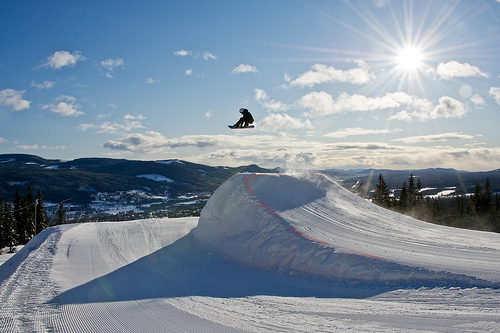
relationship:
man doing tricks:
[235, 106, 255, 122] [208, 104, 259, 137]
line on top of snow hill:
[237, 167, 308, 237] [212, 168, 427, 279]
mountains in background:
[75, 156, 173, 183] [26, 146, 220, 176]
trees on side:
[0, 209, 41, 246] [3, 245, 30, 274]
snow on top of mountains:
[96, 308, 269, 323] [75, 156, 173, 183]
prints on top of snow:
[246, 306, 308, 319] [96, 308, 269, 323]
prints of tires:
[246, 306, 308, 319] [236, 307, 313, 318]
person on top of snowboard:
[235, 106, 255, 122] [219, 123, 259, 135]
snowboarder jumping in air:
[197, 93, 263, 135] [203, 48, 296, 74]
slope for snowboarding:
[285, 172, 396, 243] [219, 123, 259, 135]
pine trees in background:
[373, 180, 438, 215] [26, 146, 220, 176]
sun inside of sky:
[399, 52, 430, 85] [254, 8, 452, 124]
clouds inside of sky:
[299, 63, 390, 114] [254, 8, 452, 124]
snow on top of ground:
[96, 308, 269, 323] [124, 282, 218, 322]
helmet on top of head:
[240, 108, 243, 113] [238, 108, 248, 112]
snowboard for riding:
[219, 123, 259, 135] [229, 109, 256, 132]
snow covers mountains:
[96, 308, 269, 323] [75, 156, 173, 183]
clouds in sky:
[299, 63, 390, 114] [254, 8, 452, 124]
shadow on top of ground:
[85, 254, 294, 306] [124, 282, 218, 322]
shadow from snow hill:
[85, 254, 294, 306] [212, 168, 427, 279]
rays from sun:
[325, 48, 376, 74] [399, 52, 430, 85]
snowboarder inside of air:
[197, 93, 263, 135] [203, 48, 296, 74]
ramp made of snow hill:
[237, 170, 331, 191] [212, 168, 427, 279]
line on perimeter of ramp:
[237, 167, 308, 237] [237, 170, 331, 191]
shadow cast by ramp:
[85, 254, 294, 306] [237, 170, 331, 191]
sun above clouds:
[399, 52, 430, 85] [299, 63, 390, 114]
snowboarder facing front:
[197, 93, 263, 135] [227, 109, 240, 126]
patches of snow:
[175, 301, 209, 321] [96, 308, 269, 323]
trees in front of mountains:
[0, 209, 41, 246] [75, 156, 173, 183]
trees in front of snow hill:
[0, 209, 41, 246] [212, 168, 427, 279]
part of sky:
[67, 1, 128, 13] [254, 8, 452, 124]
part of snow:
[60, 226, 118, 246] [96, 308, 269, 323]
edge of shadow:
[21, 238, 47, 250] [85, 254, 294, 306]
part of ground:
[129, 314, 186, 323] [124, 282, 218, 322]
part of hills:
[73, 170, 92, 180] [12, 150, 179, 208]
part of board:
[247, 125, 255, 130] [224, 122, 253, 129]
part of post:
[58, 220, 64, 223] [58, 203, 78, 221]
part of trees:
[19, 192, 41, 202] [0, 209, 41, 246]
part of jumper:
[242, 116, 251, 121] [226, 104, 259, 130]